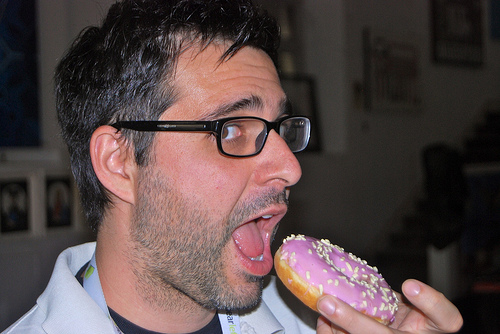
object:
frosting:
[278, 231, 400, 322]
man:
[1, 0, 466, 333]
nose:
[253, 134, 303, 188]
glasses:
[108, 114, 315, 159]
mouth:
[218, 198, 290, 281]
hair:
[45, 0, 281, 234]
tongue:
[232, 222, 269, 262]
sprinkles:
[367, 306, 385, 321]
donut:
[270, 233, 401, 332]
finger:
[397, 277, 462, 333]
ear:
[86, 125, 133, 205]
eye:
[208, 118, 245, 143]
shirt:
[0, 239, 328, 333]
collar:
[34, 241, 286, 333]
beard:
[126, 165, 288, 315]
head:
[50, 0, 312, 313]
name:
[223, 312, 239, 333]